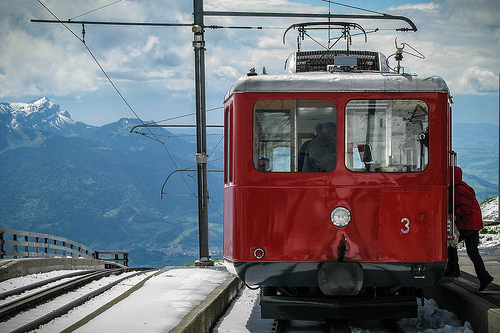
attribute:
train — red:
[210, 69, 469, 300]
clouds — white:
[66, 13, 228, 88]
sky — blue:
[4, 3, 498, 141]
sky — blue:
[3, 1, 498, 161]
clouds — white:
[123, 37, 165, 68]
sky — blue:
[2, 7, 494, 180]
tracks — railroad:
[2, 264, 154, 330]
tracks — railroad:
[269, 313, 405, 331]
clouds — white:
[9, 30, 191, 112]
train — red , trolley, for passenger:
[221, 45, 461, 320]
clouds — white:
[3, 3, 498, 91]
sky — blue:
[93, 22, 298, 73]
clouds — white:
[0, 14, 492, 92]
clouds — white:
[7, 1, 497, 123]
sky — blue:
[2, 2, 495, 125]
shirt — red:
[451, 181, 485, 238]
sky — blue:
[14, 13, 485, 143]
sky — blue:
[5, 11, 485, 155]